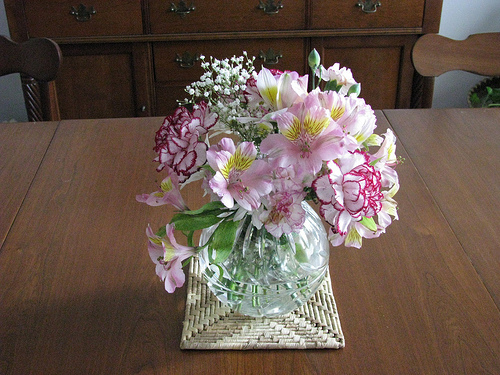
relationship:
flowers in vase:
[123, 35, 413, 251] [196, 195, 338, 322]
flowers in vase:
[153, 47, 400, 239] [197, 201, 331, 321]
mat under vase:
[175, 249, 347, 367] [181, 198, 336, 320]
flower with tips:
[313, 150, 383, 232] [338, 160, 387, 209]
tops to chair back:
[414, 25, 496, 75] [0, 34, 62, 83]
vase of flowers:
[144, 201, 403, 318] [114, 40, 461, 315]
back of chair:
[411, 13, 485, 100] [404, 16, 499, 90]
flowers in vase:
[145, 57, 436, 285] [198, 201, 330, 318]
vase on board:
[198, 201, 330, 318] [0, 108, 500, 372]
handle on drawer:
[67, 2, 99, 20] [18, 1, 143, 42]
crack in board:
[0, 116, 69, 242] [0, 108, 500, 372]